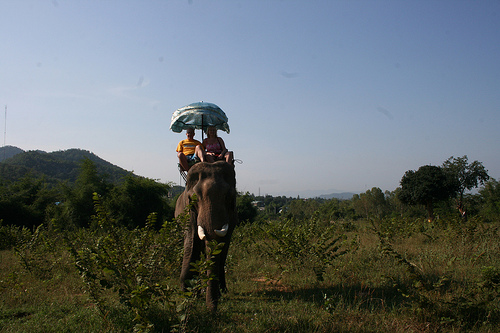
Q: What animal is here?
A: Elephant.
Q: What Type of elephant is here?
A: African.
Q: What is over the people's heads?
A: Umbrella.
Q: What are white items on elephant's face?
A: Tusks.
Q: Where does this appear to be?
A: Savannah.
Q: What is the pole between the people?
A: Umbrella.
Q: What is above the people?
A: Umbrella.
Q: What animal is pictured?
A: Elephant.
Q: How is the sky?
A: Clear.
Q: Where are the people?
A: On elephant.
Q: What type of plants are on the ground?
A: Shrubs.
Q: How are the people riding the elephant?
A: Saddle.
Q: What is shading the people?
A: Umbrella.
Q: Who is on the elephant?
A: Man and woman.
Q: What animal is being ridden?
A: Elephant.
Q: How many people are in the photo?
A: Two.